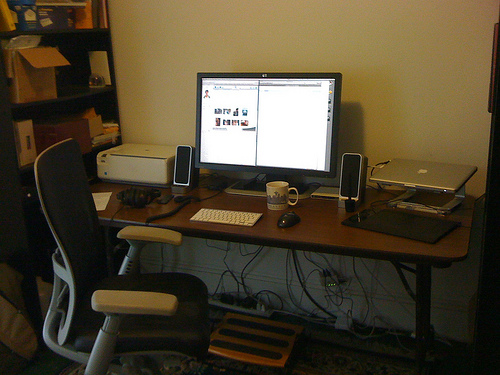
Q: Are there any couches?
A: No, there are no couches.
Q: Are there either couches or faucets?
A: No, there are no couches or faucets.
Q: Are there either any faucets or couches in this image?
A: No, there are no couches or faucets.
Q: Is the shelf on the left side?
A: Yes, the shelf is on the left of the image.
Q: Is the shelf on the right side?
A: No, the shelf is on the left of the image.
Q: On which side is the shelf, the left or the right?
A: The shelf is on the left of the image.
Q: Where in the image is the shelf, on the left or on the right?
A: The shelf is on the left of the image.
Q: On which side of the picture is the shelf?
A: The shelf is on the left of the image.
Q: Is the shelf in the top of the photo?
A: Yes, the shelf is in the top of the image.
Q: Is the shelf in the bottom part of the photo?
A: No, the shelf is in the top of the image.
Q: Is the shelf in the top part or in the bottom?
A: The shelf is in the top of the image.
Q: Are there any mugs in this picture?
A: Yes, there is a mug.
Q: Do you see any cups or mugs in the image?
A: Yes, there is a mug.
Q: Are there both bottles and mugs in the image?
A: No, there is a mug but no bottles.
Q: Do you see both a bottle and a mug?
A: No, there is a mug but no bottles.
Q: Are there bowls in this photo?
A: No, there are no bowls.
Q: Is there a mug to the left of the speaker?
A: Yes, there is a mug to the left of the speaker.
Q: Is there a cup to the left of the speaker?
A: No, there is a mug to the left of the speaker.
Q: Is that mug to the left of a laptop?
A: No, the mug is to the left of the speaker.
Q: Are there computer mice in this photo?
A: Yes, there is a computer mouse.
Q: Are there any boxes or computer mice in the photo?
A: Yes, there is a computer mouse.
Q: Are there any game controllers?
A: No, there are no game controllers.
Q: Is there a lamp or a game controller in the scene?
A: No, there are no game controllers or lamps.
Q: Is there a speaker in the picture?
A: Yes, there is a speaker.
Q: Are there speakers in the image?
A: Yes, there is a speaker.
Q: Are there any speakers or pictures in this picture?
A: Yes, there is a speaker.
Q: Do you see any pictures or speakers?
A: Yes, there is a speaker.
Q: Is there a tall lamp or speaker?
A: Yes, there is a tall speaker.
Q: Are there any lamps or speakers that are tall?
A: Yes, the speaker is tall.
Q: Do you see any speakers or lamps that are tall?
A: Yes, the speaker is tall.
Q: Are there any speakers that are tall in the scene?
A: Yes, there is a tall speaker.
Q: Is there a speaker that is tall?
A: Yes, there is a speaker that is tall.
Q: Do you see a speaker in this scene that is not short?
A: Yes, there is a tall speaker.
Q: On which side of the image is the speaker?
A: The speaker is on the right of the image.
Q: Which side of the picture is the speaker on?
A: The speaker is on the right of the image.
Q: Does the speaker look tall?
A: Yes, the speaker is tall.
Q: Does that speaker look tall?
A: Yes, the speaker is tall.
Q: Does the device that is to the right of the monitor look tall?
A: Yes, the speaker is tall.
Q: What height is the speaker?
A: The speaker is tall.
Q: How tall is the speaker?
A: The speaker is tall.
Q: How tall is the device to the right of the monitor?
A: The speaker is tall.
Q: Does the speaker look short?
A: No, the speaker is tall.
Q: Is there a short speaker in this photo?
A: No, there is a speaker but it is tall.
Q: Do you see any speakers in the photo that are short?
A: No, there is a speaker but it is tall.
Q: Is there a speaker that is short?
A: No, there is a speaker but it is tall.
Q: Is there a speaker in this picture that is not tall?
A: No, there is a speaker but it is tall.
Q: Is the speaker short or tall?
A: The speaker is tall.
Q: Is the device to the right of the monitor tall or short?
A: The speaker is tall.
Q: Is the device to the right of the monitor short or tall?
A: The speaker is tall.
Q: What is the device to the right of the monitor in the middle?
A: The device is a speaker.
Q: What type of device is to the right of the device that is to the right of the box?
A: The device is a speaker.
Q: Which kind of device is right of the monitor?
A: The device is a speaker.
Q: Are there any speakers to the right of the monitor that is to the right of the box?
A: Yes, there is a speaker to the right of the monitor.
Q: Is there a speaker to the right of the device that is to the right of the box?
A: Yes, there is a speaker to the right of the monitor.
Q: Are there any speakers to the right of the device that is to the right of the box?
A: Yes, there is a speaker to the right of the monitor.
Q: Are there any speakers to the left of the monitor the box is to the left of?
A: No, the speaker is to the right of the monitor.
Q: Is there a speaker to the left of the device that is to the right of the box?
A: No, the speaker is to the right of the monitor.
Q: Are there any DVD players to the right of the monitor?
A: No, there is a speaker to the right of the monitor.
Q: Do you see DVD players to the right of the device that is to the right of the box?
A: No, there is a speaker to the right of the monitor.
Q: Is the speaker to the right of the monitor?
A: Yes, the speaker is to the right of the monitor.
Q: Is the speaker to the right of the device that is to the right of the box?
A: Yes, the speaker is to the right of the monitor.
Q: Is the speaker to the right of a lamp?
A: No, the speaker is to the right of the monitor.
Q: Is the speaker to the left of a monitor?
A: No, the speaker is to the right of a monitor.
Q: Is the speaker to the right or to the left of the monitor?
A: The speaker is to the right of the monitor.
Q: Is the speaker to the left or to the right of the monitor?
A: The speaker is to the right of the monitor.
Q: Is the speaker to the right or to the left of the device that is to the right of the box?
A: The speaker is to the right of the monitor.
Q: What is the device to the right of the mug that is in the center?
A: The device is a speaker.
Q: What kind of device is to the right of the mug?
A: The device is a speaker.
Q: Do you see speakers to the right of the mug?
A: Yes, there is a speaker to the right of the mug.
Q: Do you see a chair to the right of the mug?
A: No, there is a speaker to the right of the mug.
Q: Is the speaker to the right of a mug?
A: Yes, the speaker is to the right of a mug.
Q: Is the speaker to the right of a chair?
A: No, the speaker is to the right of a mug.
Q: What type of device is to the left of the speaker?
A: The device is a monitor.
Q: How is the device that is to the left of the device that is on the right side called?
A: The device is a monitor.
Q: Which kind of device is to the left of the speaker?
A: The device is a monitor.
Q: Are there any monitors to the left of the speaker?
A: Yes, there is a monitor to the left of the speaker.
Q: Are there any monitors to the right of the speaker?
A: No, the monitor is to the left of the speaker.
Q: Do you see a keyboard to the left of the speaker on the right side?
A: No, there is a monitor to the left of the speaker.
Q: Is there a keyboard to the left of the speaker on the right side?
A: No, there is a monitor to the left of the speaker.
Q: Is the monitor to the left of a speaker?
A: Yes, the monitor is to the left of a speaker.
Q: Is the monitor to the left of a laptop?
A: No, the monitor is to the left of a speaker.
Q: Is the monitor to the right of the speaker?
A: No, the monitor is to the left of the speaker.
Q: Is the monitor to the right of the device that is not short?
A: No, the monitor is to the left of the speaker.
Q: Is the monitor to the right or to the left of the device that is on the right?
A: The monitor is to the left of the speaker.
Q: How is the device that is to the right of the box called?
A: The device is a monitor.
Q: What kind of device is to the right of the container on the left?
A: The device is a monitor.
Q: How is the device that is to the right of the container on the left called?
A: The device is a monitor.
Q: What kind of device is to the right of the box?
A: The device is a monitor.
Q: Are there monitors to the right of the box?
A: Yes, there is a monitor to the right of the box.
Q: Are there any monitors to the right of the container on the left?
A: Yes, there is a monitor to the right of the box.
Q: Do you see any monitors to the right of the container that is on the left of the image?
A: Yes, there is a monitor to the right of the box.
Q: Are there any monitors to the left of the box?
A: No, the monitor is to the right of the box.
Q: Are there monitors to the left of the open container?
A: No, the monitor is to the right of the box.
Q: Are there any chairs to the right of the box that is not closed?
A: No, there is a monitor to the right of the box.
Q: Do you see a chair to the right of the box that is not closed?
A: No, there is a monitor to the right of the box.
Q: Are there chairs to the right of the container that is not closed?
A: No, there is a monitor to the right of the box.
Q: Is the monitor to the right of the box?
A: Yes, the monitor is to the right of the box.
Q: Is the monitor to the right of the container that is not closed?
A: Yes, the monitor is to the right of the box.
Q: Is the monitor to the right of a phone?
A: No, the monitor is to the right of the box.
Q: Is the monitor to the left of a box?
A: No, the monitor is to the right of a box.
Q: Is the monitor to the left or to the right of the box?
A: The monitor is to the right of the box.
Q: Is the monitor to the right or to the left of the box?
A: The monitor is to the right of the box.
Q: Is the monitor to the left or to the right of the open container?
A: The monitor is to the right of the box.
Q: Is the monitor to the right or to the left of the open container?
A: The monitor is to the right of the box.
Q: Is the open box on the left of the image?
A: Yes, the box is on the left of the image.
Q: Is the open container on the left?
A: Yes, the box is on the left of the image.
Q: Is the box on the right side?
A: No, the box is on the left of the image.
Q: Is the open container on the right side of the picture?
A: No, the box is on the left of the image.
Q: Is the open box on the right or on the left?
A: The box is on the left of the image.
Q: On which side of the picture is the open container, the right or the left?
A: The box is on the left of the image.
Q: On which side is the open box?
A: The box is on the left of the image.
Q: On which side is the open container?
A: The box is on the left of the image.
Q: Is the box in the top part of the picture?
A: Yes, the box is in the top of the image.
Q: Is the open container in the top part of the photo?
A: Yes, the box is in the top of the image.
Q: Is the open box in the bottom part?
A: No, the box is in the top of the image.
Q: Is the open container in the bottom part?
A: No, the box is in the top of the image.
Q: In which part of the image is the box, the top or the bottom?
A: The box is in the top of the image.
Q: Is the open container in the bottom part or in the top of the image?
A: The box is in the top of the image.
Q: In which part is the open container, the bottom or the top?
A: The box is in the top of the image.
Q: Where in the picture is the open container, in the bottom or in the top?
A: The box is in the top of the image.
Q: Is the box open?
A: Yes, the box is open.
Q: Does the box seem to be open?
A: Yes, the box is open.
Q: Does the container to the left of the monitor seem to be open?
A: Yes, the box is open.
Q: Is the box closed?
A: No, the box is open.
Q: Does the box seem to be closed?
A: No, the box is open.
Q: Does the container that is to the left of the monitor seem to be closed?
A: No, the box is open.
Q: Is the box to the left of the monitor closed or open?
A: The box is open.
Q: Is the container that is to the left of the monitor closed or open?
A: The box is open.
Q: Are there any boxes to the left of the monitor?
A: Yes, there is a box to the left of the monitor.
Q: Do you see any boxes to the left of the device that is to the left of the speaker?
A: Yes, there is a box to the left of the monitor.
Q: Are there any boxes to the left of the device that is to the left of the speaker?
A: Yes, there is a box to the left of the monitor.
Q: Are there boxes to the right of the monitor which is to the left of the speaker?
A: No, the box is to the left of the monitor.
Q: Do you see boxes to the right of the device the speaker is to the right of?
A: No, the box is to the left of the monitor.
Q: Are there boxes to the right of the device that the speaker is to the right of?
A: No, the box is to the left of the monitor.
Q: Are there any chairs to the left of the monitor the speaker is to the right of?
A: No, there is a box to the left of the monitor.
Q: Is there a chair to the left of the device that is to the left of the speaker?
A: No, there is a box to the left of the monitor.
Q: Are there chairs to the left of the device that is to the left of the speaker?
A: No, there is a box to the left of the monitor.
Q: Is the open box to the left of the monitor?
A: Yes, the box is to the left of the monitor.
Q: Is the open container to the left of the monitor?
A: Yes, the box is to the left of the monitor.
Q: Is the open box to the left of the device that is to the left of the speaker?
A: Yes, the box is to the left of the monitor.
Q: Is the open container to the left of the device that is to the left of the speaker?
A: Yes, the box is to the left of the monitor.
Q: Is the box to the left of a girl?
A: No, the box is to the left of the monitor.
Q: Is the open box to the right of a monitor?
A: No, the box is to the left of a monitor.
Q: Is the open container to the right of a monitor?
A: No, the box is to the left of a monitor.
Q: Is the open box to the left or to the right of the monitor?
A: The box is to the left of the monitor.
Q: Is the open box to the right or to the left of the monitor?
A: The box is to the left of the monitor.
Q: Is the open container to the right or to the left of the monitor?
A: The box is to the left of the monitor.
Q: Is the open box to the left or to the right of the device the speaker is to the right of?
A: The box is to the left of the monitor.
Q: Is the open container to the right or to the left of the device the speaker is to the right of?
A: The box is to the left of the monitor.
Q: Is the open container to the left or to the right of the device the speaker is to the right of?
A: The box is to the left of the monitor.